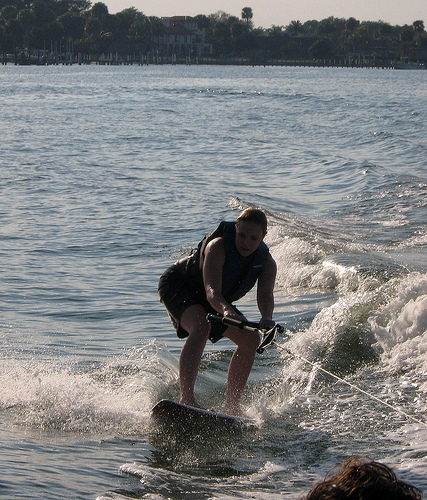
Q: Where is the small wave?
A: In the water.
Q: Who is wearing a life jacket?
A: The person.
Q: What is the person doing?
A: Wakeboarding.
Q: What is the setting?
A: A lake.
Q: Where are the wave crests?
A: In the lake.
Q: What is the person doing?
A: Wakeboarding.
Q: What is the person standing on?
A: A wakeboard.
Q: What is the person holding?
A: A tow rope.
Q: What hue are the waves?
A: Blue.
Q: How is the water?
A: Calm.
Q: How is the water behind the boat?
A: Rough.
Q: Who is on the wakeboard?
A: A woman.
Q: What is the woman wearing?
A: A life vest.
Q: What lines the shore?
A: Trees and houses.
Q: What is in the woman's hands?
A: A handle.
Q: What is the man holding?
A: Wire of a jet ski.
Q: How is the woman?
A: She is crouching over.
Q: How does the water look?
A: It has white waves.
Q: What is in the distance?
A: Trees and buildings.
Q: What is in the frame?
A: A large body of water.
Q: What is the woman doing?
A: She is surfing.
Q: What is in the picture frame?
A: Blue water.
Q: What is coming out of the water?
A: Poles are coming out of the water.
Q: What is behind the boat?
A: A wake.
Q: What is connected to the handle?
A: The rope.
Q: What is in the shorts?
A: The woman boarding.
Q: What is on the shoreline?
A: The trees.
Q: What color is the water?
A: Blue and white.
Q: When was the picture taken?
A: Daytime.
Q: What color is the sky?
A: Gray.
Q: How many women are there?
A: One.